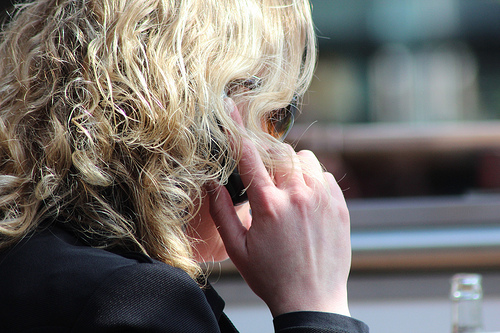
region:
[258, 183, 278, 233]
part of a finger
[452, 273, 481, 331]
a small clear bottle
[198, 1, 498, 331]
the background is blurry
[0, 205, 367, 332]
the shirt is dark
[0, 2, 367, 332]
woman talking on phone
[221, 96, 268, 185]
finger of a woman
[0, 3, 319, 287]
the hair is blonde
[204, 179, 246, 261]
thumb of a woman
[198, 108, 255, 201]
phone in the hand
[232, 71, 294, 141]
woman is wearing glasses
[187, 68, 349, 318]
the skin is pale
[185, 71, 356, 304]
a person holding a cellular phone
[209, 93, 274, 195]
the finger of a person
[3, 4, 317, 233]
a woman with blonde hair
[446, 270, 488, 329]
the top of a glass bottle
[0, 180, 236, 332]
a black suit jacket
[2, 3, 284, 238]
a woman with curly hair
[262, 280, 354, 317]
the wrist of a person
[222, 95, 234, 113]
a person's finger nail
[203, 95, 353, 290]
Right white hand of a woman.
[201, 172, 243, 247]
Thumb of a right hand.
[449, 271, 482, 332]
The glass top of a bottle.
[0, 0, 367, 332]
A blonde haired woman talking on a phone.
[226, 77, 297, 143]
Sunglasses on a woman.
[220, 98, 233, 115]
Fingernail on a pointer finger in the womans hair.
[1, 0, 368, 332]
A blonde woman on the phone in a black coat.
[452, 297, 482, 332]
The neck of a glass bottle.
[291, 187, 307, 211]
Middle knuckle on a right hand.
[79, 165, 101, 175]
part of a hair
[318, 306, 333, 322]
edge of a coat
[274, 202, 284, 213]
part of a finger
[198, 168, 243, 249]
Finger of a woman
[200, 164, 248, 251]
Finger of a woman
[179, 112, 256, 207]
The woman has her cellphone in her hand.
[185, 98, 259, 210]
The woman has her cellphone in her hand.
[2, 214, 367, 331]
The woman is wearing a black jacket.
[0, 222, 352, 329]
The woman is wearing a black jacket.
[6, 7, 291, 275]
The woman has blonde curly hair.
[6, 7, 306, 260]
The woman has blonde curly hair.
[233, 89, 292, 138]
The woman is wearing brown sunglasses.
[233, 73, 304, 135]
The woman is wearing brown sunglasses.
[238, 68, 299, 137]
The woman is wearing brown sunglasses.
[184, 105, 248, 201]
The woman's cellphone is black.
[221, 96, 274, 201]
Finger up the highest.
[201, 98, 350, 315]
A right hand on a woman.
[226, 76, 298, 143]
A pair of sunglasses.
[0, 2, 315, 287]
Blonde curly hair on a woman.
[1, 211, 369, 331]
Black coat on a woman.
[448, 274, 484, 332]
A clear bottle top.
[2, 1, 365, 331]
Woman with blonde hair and black jacket.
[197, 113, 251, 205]
Black cell phone against a head.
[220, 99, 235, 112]
Fingernail on a finger up the highest.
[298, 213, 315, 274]
tendon in a hand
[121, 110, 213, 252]
curls in blonde hair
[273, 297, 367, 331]
cuff of a shirt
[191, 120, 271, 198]
small black cell phone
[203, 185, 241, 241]
thumb of a woman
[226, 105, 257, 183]
index finger of a woman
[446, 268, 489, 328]
top of a glass bottle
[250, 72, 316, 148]
sunglasses on a face